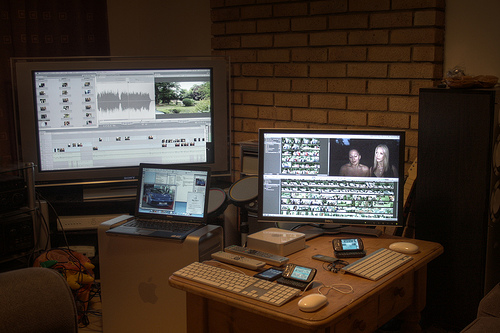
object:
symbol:
[135, 277, 158, 307]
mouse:
[296, 291, 329, 311]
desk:
[164, 229, 450, 333]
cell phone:
[252, 264, 286, 280]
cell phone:
[279, 262, 319, 282]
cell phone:
[329, 237, 365, 259]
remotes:
[212, 250, 269, 271]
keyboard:
[123, 219, 199, 235]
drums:
[226, 176, 261, 203]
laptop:
[104, 163, 213, 243]